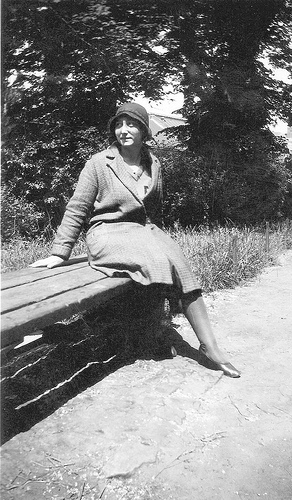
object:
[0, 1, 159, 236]
trees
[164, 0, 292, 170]
trees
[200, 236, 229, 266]
grass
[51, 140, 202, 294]
long jacket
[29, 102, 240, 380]
woman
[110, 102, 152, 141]
hat